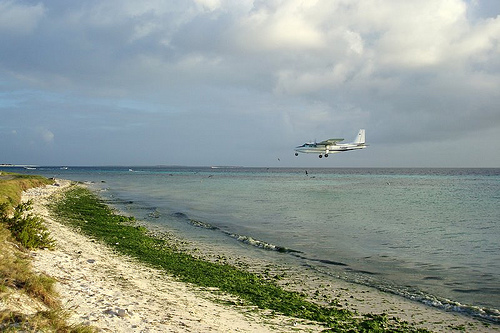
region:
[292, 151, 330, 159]
small, black bi-plane wheels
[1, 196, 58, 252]
little green bush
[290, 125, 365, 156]
small white and blue bi-plane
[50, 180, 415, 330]
a lot washed up seaweed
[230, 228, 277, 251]
little white cap on a small wave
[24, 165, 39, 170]
speed boat in the background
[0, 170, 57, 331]
area of grassy land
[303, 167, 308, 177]
buoy out in the sea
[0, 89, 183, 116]
blue sky peeking through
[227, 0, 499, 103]
bunch of fluffy white clouds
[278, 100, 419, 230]
A plane is visible.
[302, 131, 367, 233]
A plane is visible.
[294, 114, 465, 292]
A plane is visible.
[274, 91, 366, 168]
A plane is visible.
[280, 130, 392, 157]
Plane hovering over the water.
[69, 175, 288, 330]
Green grass growing on sand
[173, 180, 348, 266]
Small wave in ocean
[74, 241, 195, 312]
Tracks in the sand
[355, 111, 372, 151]
Tail fin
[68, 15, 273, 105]
Cloudy sky no blue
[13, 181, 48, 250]
Plants growing on the side of the hill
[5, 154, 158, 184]
Open ocean with no land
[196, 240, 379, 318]
Small rocks on sand of beach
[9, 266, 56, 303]
Dead brown grass on beach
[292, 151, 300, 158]
a black wheel of a plane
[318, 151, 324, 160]
a black wheel of a plane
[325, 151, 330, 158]
a black wheel of a plane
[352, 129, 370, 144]
a white tail of a plane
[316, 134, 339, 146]
a blue and white wing of a plane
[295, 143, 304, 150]
a blue and white nose of a plane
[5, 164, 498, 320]
blue and green ocean water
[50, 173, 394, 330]
a line of green seaweed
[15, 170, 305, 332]
strech of white sand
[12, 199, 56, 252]
a green leafy bush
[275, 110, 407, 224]
The plane is visible.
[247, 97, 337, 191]
The plane is visible.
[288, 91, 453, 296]
The plane is visible.